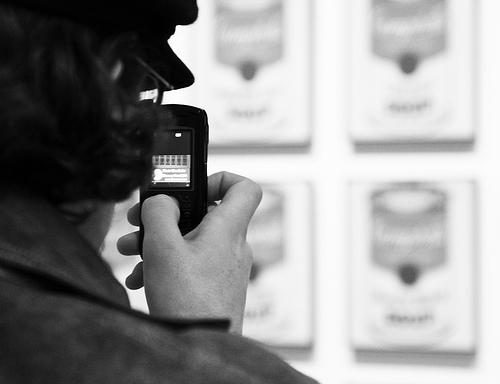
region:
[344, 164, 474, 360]
faded campbell's soup sign on wall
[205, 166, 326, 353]
blurry campbell's soup sign on wall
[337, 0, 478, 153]
blurry campbell's soup sign on wall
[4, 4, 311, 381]
person standing in front of wall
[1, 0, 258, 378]
man standing in shadow in front of wall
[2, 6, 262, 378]
dark man holding black object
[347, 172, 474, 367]
campbell's soup sign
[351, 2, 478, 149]
blurred campbell soup can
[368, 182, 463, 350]
campbell soup can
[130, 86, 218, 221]
black object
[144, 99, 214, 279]
an old cell phone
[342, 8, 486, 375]
artwork displaying soup cans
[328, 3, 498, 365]
posters of cans of soup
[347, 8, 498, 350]
paintings of campbell soup cans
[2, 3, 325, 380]
the man is taking a photo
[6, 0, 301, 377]
he is snapping a photo with his phone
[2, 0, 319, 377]
he is taking a photo with his cell phone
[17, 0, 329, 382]
the man is wearing a hat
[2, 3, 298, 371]
the man is wearing glasses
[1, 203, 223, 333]
the collar to his jacket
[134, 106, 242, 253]
a cell phone in hand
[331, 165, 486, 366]
a sign on a wall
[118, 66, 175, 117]
a eye glass lens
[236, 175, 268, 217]
a person's knucle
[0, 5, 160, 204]
brown shaggy hair on person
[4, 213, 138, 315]
a person's shirt collar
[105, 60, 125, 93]
a person's ear sticking out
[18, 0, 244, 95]
person wearing a black hat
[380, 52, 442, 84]
a black circle on the sign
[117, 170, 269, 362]
a white person's hand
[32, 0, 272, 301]
a person on a ceil phone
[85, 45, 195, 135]
black glasses on a persons head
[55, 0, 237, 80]
a black hat on person head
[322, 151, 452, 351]
soup cans pictures on the wall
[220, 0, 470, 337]
two rolls of soup can pictures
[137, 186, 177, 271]
thrum of a hand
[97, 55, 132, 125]
part of a persons ear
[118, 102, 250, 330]
a hand holding a ceil phone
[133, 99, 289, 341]
a persons right hand holding a ceil phone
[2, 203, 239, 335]
the collar of a coat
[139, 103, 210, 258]
Cell phon has image on the screen.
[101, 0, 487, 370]
Background pictures are blurry not clear.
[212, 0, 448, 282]
Four objects with black circle look identical.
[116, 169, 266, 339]
Four fingers and a thumb hold the object.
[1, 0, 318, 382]
A man is looking at the cell phone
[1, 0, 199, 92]
The head is covered by a hat.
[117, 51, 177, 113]
Glasses are on the head.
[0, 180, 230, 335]
A collar is attached to the jacket.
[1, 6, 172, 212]
The mans' hair is dark and curly.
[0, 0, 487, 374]
The images are in black and white.